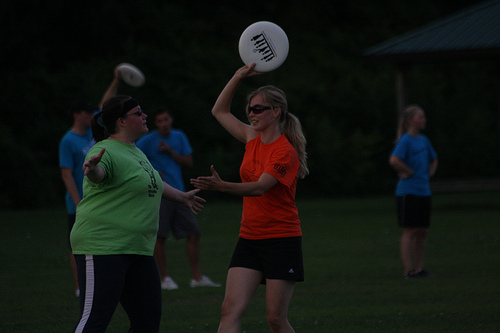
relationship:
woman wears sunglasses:
[190, 58, 317, 332] [243, 102, 280, 113]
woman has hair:
[190, 58, 317, 332] [246, 80, 313, 182]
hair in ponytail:
[246, 80, 313, 182] [282, 106, 313, 186]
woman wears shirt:
[190, 58, 317, 332] [232, 128, 306, 245]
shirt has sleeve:
[232, 128, 306, 245] [261, 143, 299, 187]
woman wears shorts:
[190, 58, 317, 332] [223, 229, 311, 288]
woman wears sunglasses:
[66, 91, 173, 333] [121, 104, 145, 123]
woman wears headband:
[66, 91, 173, 333] [100, 94, 141, 119]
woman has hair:
[66, 91, 173, 333] [84, 91, 138, 149]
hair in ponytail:
[84, 91, 138, 149] [86, 108, 109, 148]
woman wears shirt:
[66, 91, 173, 333] [65, 132, 165, 255]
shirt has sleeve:
[65, 132, 165, 255] [79, 143, 116, 186]